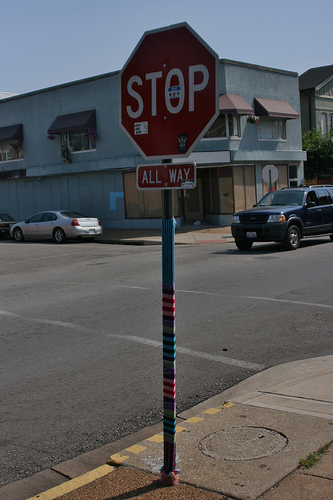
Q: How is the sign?
A: Eight sided.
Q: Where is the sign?
A: On post.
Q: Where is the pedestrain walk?
A: The road.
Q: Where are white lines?
A: On the road.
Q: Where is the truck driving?
A: On road.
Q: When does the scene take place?
A: During the daytime.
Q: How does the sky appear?
A: Blue and clear.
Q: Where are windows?
A: On a building.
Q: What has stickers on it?
A: Stop sign.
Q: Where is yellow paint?
A: On the curb.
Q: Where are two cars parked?
A: On side of the road.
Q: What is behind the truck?
A: A stop sign.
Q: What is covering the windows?
A: Paper.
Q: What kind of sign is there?
A: A stop sign.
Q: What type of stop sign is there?
A: A stop all way sign.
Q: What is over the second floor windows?
A: Awnings.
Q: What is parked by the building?
A: A car.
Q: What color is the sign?
A: Red.